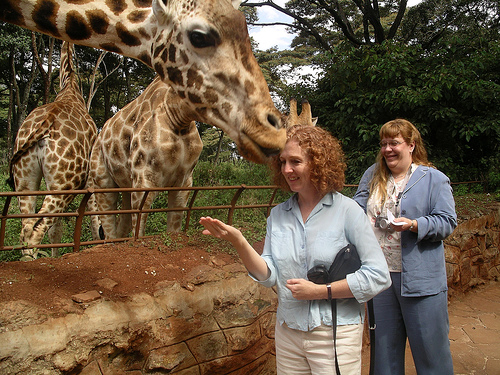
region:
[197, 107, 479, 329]
woman feeding a giraffe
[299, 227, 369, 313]
woman holding a black purse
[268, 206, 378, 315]
woman wearing a blue button-down shirt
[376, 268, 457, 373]
woman wearing blue pants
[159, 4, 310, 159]
a giraffe kissing a woman's hair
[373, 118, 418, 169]
a red-headed woman wearing glasses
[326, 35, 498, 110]
green lush foliage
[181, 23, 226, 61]
the eye of a giraffe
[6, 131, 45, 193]
a giraffe's tail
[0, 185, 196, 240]
a small metal fence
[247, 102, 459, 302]
two red haired women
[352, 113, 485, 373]
woman in blue pant suit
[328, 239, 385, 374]
purse with long black strap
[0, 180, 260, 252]
metal fence at zoo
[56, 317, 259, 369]
stone wall of pen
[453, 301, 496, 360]
cobblestone pathway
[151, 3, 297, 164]
giraffe getting too friendly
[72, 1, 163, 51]
brown and white spots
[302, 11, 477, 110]
green trees in background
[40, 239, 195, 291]
reddish brown dirt along wall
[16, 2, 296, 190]
A giraffe leans over the wall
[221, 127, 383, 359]
Woman in blue shirt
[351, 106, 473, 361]
A woman with black glasses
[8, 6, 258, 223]
Three giraffes inside an enclosure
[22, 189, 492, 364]
A rock wall with a dirt planter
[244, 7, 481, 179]
Trees behind the rock and steel wall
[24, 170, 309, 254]
A brown metal gate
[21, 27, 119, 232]
The giraffe is walking away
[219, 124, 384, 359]
The woman is carrying two black bags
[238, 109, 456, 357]
The two woman are standing near the wall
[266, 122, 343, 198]
the head of a woman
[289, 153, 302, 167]
the eye of a woman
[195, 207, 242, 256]
the hand of a woman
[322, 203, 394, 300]
the arm of a woman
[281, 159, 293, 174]
the nose of a woman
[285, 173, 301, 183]
the mouth of a woman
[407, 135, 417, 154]
the ear of a woman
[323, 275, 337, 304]
a brown wrist watch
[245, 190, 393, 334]
a light blue shirt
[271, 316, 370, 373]
a pair of white pants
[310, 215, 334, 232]
part of a shirt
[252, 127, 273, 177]
mouth of a giraffe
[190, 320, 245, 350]
side of a path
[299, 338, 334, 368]
part of a trouser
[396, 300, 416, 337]
part of a trouser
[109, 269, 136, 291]
part of some sand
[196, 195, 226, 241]
part of a hand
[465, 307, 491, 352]
part of a floor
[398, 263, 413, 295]
edge of a coat